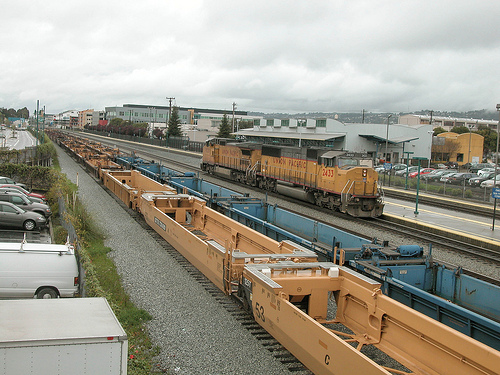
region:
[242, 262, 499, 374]
a yellow container car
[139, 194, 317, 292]
a yellow container car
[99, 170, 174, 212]
a yellow container car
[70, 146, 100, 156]
a yellow container car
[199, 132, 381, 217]
a double engine locomotive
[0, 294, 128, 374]
a white trailer of a truck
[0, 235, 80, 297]
a white van parked near the tracks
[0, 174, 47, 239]
a row of parked cars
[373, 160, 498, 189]
cars in a parking lot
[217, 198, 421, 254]
a blue train car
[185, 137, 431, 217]
A train on tracks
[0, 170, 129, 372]
Cars parked in a lot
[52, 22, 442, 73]
a loudy sky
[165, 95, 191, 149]
A telephone pole with a tree next to it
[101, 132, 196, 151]
A chain linked fence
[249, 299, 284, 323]
The number 53 painted on an unconstructed train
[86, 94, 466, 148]
An industrial park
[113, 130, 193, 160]
Empty train tracks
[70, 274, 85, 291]
A tail light on the back of a van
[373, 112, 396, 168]
A street lamp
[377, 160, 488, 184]
cars parked in lot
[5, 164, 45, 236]
cars parked in a row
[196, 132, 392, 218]
yellow train on tracks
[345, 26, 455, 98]
gray clouds in daytime sky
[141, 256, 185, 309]
gravel on side of tracks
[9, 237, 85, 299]
white van backed into parking spot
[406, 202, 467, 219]
yellow line on asphalt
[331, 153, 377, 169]
two windows on front of train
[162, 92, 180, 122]
telephone pole in distance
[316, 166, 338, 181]
red number on side of train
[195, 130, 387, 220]
Moving train on the tracks.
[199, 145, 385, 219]
Yellow train moving on the railroad tracks.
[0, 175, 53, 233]
Automobiles in a parking lot.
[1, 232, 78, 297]
White van backed in a parking stall.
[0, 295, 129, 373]
White trailer to a truck.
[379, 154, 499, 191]
Cars parked in the parking lot.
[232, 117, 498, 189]
White building with cars in the parking lot.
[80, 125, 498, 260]
Yellow train moving on rail tracks.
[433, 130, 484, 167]
Yellow business establishment behind a white building.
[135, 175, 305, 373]
Grey gravel beside the tracks.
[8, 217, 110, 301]
White van near fence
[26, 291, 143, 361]
Back of white truck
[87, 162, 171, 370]
Gravel near tracks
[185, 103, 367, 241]
Yellow train cars on tracks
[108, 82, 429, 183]
Many buildings on the right side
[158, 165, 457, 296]
Blue train cars lined up in a row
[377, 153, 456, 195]
Cars parked in lot across from train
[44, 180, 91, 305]
Fence near cars parked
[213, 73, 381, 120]
Sky is cloudy and overcast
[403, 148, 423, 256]
Green posts on road